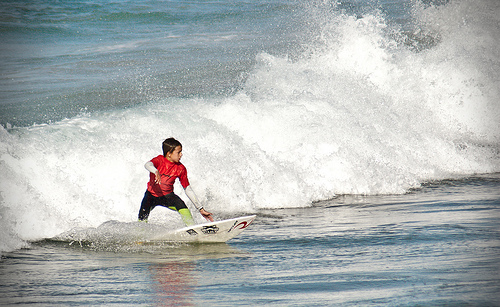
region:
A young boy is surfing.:
[127, 130, 257, 239]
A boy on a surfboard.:
[113, 132, 261, 251]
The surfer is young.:
[120, 129, 260, 249]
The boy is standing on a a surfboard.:
[99, 124, 262, 244]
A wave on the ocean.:
[16, 24, 498, 222]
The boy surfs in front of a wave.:
[23, 112, 247, 254]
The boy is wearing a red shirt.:
[106, 124, 270, 254]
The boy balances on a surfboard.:
[108, 132, 264, 246]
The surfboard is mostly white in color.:
[127, 208, 264, 263]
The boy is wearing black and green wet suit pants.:
[103, 135, 283, 246]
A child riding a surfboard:
[142, 135, 254, 244]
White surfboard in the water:
[148, 213, 257, 240]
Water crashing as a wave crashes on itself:
[16, 5, 498, 263]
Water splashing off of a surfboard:
[65, 217, 187, 246]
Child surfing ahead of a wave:
[129, 137, 256, 244]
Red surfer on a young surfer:
[139, 155, 189, 195]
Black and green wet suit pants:
[137, 190, 193, 226]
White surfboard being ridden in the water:
[139, 213, 257, 244]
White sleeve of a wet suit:
[184, 183, 203, 209]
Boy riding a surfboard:
[127, 138, 257, 242]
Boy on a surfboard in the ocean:
[130, 133, 257, 251]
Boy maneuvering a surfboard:
[124, 135, 259, 239]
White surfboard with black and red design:
[141, 210, 258, 250]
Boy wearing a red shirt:
[133, 137, 213, 230]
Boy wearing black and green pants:
[134, 135, 217, 232]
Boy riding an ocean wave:
[114, 134, 254, 244]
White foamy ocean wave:
[2, 4, 497, 254]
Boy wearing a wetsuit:
[135, 134, 213, 242]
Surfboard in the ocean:
[135, 210, 257, 245]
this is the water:
[125, 244, 256, 305]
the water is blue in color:
[300, 242, 382, 305]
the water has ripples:
[295, 223, 430, 265]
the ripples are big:
[309, 213, 401, 241]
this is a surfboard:
[165, 213, 266, 239]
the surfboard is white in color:
[221, 222, 233, 229]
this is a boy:
[145, 135, 217, 225]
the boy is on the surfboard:
[141, 134, 215, 229]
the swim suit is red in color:
[164, 162, 173, 184]